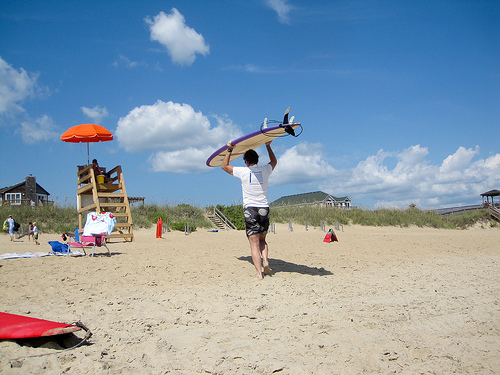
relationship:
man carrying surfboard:
[220, 135, 286, 283] [203, 104, 308, 178]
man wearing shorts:
[220, 135, 286, 283] [241, 204, 273, 243]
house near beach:
[1, 172, 52, 212] [1, 200, 499, 374]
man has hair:
[220, 135, 286, 283] [241, 146, 263, 166]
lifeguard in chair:
[83, 157, 111, 191] [74, 157, 138, 243]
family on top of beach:
[3, 212, 42, 249] [1, 200, 499, 374]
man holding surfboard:
[220, 135, 286, 283] [203, 104, 308, 178]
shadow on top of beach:
[234, 250, 336, 282] [1, 200, 499, 374]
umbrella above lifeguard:
[58, 119, 115, 167] [83, 157, 111, 191]